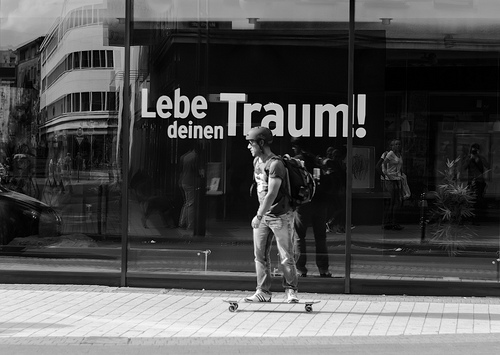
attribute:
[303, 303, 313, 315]
wheel — Black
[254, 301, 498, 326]
shadow — Black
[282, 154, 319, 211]
backpack — Black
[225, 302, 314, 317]
wheels — Black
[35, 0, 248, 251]
reflection — Clear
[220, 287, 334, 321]
board — Black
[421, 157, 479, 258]
plant — Green, Indoors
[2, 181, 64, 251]
car — Parked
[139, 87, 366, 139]
words — White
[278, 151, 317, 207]
backpack — Dark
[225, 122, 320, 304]
man — Skating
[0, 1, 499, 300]
building — Worded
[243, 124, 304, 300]
man — Skating